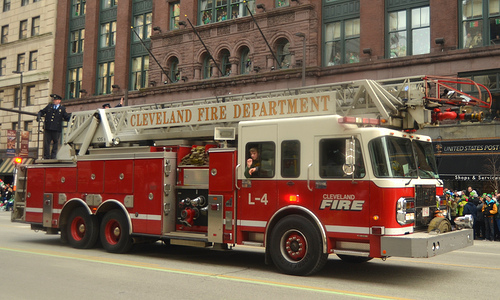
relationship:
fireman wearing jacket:
[35, 93, 70, 156] [33, 97, 73, 129]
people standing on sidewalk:
[439, 186, 500, 244] [461, 239, 485, 249]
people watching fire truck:
[440, 181, 498, 234] [20, 72, 494, 276]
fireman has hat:
[35, 93, 70, 156] [48, 92, 63, 103]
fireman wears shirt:
[35, 93, 70, 156] [52, 103, 60, 110]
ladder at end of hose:
[18, 62, 483, 254] [429, 95, 484, 124]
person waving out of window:
[243, 140, 261, 175] [244, 145, 275, 177]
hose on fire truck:
[426, 212, 453, 234] [20, 72, 495, 276]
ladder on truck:
[18, 62, 483, 254] [216, 128, 417, 231]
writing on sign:
[129, 93, 329, 126] [319, 181, 371, 221]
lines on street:
[2, 244, 379, 299] [4, 206, 498, 298]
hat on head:
[47, 89, 68, 104] [49, 91, 67, 110]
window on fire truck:
[281, 140, 300, 178] [20, 72, 494, 276]